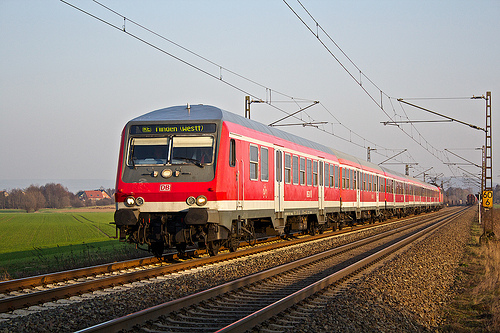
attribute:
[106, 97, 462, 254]
train — red, white-striped, white, passenger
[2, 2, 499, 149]
sky — blue, large, vast, clear, cloudless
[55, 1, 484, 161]
wires — parallel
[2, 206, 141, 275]
field — green, short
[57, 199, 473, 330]
track — empty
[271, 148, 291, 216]
doors — white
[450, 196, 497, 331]
grass — brown